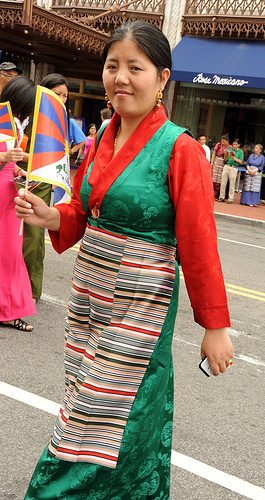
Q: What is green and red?
A: Woman's outfit.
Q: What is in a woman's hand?
A: Flag.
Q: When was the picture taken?
A: Daytime.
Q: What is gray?
A: The street.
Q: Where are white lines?
A: On the street.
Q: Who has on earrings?
A: The woman.